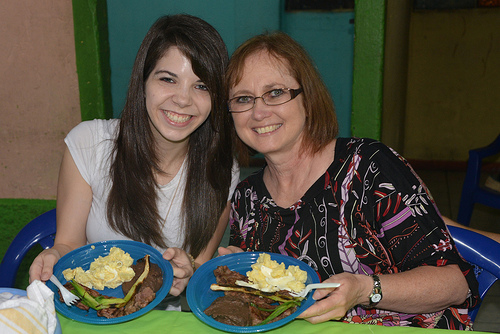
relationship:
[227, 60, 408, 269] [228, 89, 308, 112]
woman wearing eyeglasses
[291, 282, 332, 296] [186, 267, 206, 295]
fork on plate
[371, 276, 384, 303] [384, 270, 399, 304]
watch on wrist